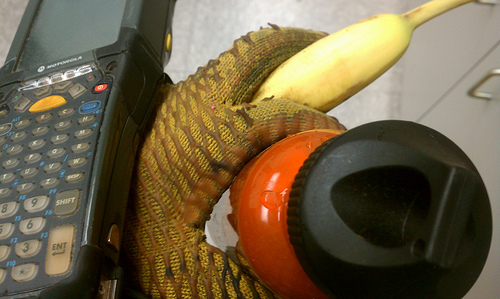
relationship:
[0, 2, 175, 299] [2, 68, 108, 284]
scanner has buttons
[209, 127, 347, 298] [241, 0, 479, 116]
cup beside banana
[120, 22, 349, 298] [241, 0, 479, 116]
glove grips banana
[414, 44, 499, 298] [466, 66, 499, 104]
door has handle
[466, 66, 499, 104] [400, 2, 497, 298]
handle on cupboard